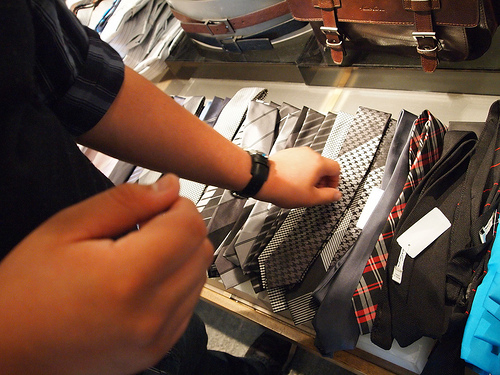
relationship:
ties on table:
[134, 69, 496, 359] [165, 8, 495, 370]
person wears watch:
[4, 0, 345, 374] [235, 149, 270, 204]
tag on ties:
[396, 196, 445, 285] [134, 69, 496, 359]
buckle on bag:
[306, 21, 450, 58] [291, 0, 498, 42]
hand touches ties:
[262, 136, 349, 213] [134, 69, 496, 359]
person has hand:
[4, 0, 345, 374] [2, 172, 227, 373]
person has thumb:
[4, 0, 345, 374] [142, 153, 184, 228]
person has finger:
[4, 0, 345, 374] [112, 199, 206, 288]